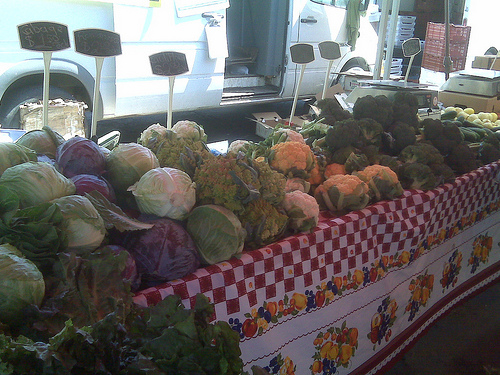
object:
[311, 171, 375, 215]
cauliflower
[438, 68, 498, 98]
scale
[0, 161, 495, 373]
tablecloth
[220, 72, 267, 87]
step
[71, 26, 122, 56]
sign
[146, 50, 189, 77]
sign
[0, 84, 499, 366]
table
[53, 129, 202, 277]
cabbage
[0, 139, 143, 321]
lettuce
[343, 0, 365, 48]
towel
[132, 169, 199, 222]
cabbage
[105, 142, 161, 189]
cabbage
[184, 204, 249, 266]
cabbage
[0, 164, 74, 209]
cabbage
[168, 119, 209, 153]
cabbage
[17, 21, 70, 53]
sign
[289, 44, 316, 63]
sign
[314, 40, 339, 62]
sign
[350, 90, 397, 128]
broccoli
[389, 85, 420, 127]
broccoli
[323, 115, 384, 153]
broccoli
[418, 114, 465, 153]
broccoli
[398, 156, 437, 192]
broccoli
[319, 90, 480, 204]
pile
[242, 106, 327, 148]
box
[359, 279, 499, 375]
street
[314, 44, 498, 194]
crates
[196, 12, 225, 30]
handle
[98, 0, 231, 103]
door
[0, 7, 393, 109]
van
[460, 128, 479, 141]
cucumber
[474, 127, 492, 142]
cucumber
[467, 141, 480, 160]
cucumber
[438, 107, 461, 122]
cucumber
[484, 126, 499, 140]
cucumber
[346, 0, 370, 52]
shirt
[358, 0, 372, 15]
mirror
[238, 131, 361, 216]
cauliflower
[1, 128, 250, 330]
cabbage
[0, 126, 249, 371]
cabbage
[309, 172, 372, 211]
cauliflower head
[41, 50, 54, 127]
stand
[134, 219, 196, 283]
cabbage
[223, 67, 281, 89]
step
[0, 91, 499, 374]
vegetables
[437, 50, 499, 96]
scale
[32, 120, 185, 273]
stack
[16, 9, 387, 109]
truck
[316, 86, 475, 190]
broccoli